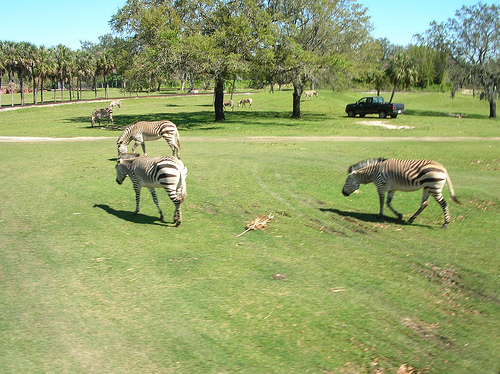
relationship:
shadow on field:
[319, 204, 434, 230] [7, 95, 489, 364]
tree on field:
[252, 5, 365, 119] [6, 244, 190, 370]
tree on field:
[162, 5, 268, 125] [6, 244, 190, 370]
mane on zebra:
[348, 155, 388, 173] [336, 152, 462, 234]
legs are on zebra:
[377, 185, 402, 222] [341, 156, 468, 201]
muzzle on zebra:
[338, 189, 353, 199] [341, 155, 457, 225]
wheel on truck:
[378, 110, 388, 117] [342, 95, 407, 119]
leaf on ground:
[235, 210, 273, 237] [0, 89, 498, 371]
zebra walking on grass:
[111, 150, 187, 225] [2, 81, 499, 370]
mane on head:
[348, 155, 388, 173] [340, 162, 360, 198]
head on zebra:
[340, 162, 360, 198] [341, 155, 457, 225]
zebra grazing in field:
[116, 120, 181, 163] [4, 110, 498, 371]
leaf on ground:
[234, 209, 275, 237] [191, 200, 335, 298]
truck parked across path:
[342, 92, 403, 120] [185, 130, 462, 145]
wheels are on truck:
[341, 108, 365, 116] [343, 93, 409, 119]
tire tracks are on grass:
[239, 154, 497, 371] [3, 140, 498, 370]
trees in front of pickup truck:
[428, 4, 500, 120] [342, 91, 406, 121]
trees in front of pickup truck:
[111, 4, 283, 124] [342, 91, 406, 121]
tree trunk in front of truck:
[287, 77, 310, 125] [333, 89, 417, 121]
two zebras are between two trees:
[221, 92, 254, 110] [108, 0, 366, 126]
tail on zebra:
[441, 165, 461, 205] [338, 155, 462, 228]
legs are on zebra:
[375, 185, 387, 219] [325, 149, 468, 234]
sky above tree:
[4, 4, 97, 36] [2, 39, 17, 107]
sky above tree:
[4, 4, 97, 36] [15, 40, 32, 101]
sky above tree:
[4, 4, 97, 36] [27, 45, 41, 107]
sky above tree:
[4, 4, 97, 36] [34, 44, 57, 100]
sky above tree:
[4, 4, 97, 36] [51, 41, 71, 98]